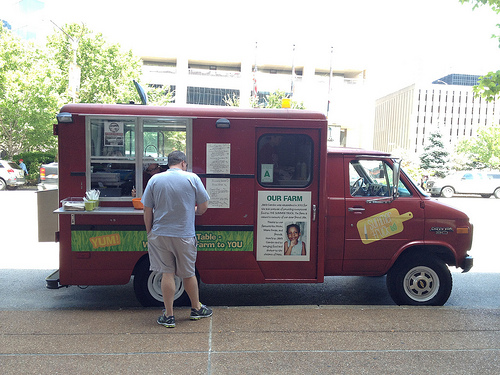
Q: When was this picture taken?
A: Daytime.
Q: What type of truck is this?
A: Food truck.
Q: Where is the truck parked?
A: Side of street.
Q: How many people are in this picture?
A: 1.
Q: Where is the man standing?
A: On sidewalk.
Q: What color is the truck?
A: Red.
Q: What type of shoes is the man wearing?
A: Sneakers.